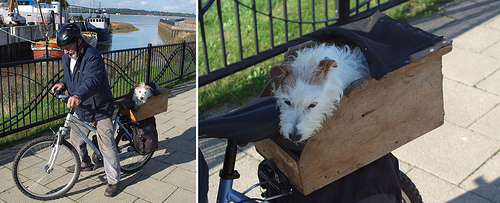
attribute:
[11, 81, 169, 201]
bike — black, back, silver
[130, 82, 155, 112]
dog — scared, white, small, brown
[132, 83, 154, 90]
ears — brown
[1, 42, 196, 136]
railings — black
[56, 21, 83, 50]
helmet — black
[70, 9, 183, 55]
water — pretty, blue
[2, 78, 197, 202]
sidewalk — stone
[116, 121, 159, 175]
tire — black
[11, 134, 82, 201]
tire — black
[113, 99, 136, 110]
seat — black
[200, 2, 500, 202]
walkway — concrete, paved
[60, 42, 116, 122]
jacket — navy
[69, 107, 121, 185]
pants — khaki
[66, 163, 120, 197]
shoes — brown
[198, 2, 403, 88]
fence — black, iron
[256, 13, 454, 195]
basket — wood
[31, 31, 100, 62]
boat — red